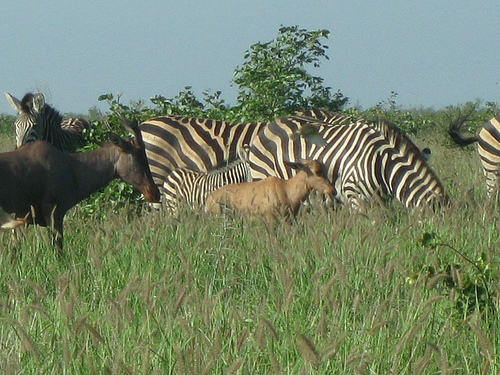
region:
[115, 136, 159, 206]
the head of an animal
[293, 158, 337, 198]
the head of an animal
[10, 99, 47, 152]
the head of an animal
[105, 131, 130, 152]
the ear of an animal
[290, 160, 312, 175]
the ear of an animal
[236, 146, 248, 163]
the ear of an animal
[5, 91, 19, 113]
the ear of an animal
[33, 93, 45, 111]
the ear of an animal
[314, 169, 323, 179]
the eye of an animal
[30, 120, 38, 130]
the eye of an animal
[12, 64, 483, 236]
the animals in the grass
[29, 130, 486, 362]
the grass the animals are standing in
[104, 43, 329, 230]
the tall bushes behind the animals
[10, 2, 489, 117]
the blue sky in the background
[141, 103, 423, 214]
the three zebras in the middle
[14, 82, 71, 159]
the zebra whose head is seen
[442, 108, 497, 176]
the only zebras tail that is seen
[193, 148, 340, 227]
the little brown animal beside the zebras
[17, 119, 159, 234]
the bigger brown animal beside the zebras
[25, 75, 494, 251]
the animals grazing in the field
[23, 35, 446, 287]
animals out in field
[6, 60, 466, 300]
different animals out in field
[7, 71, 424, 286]
variety of animals out in field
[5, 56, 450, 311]
many animals out in field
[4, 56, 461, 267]
several animals out in field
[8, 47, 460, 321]
mix of animals out in field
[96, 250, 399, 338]
patch of green grass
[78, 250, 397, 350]
patch of grass in field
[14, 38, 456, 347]
animals out in tall grass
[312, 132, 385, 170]
stripes of a zebra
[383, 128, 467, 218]
neck of a zebra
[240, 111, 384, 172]
body of a zebra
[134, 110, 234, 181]
body of a zebra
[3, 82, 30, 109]
ear of a zebra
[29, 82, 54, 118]
ear of a zebra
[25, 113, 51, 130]
eye of a zebra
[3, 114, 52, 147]
head of a zebra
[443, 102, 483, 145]
tail of a zebra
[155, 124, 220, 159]
skin of a zebra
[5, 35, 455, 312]
Animals standing in tall grass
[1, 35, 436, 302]
Zebras and ram standing in grass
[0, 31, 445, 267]
Rams standing in front of zebra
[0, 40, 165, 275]
Ram stares in front of zebra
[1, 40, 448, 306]
Zebras eating grass in background of ram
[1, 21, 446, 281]
Zebras eating grass next to bushes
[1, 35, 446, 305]
Zebras walking with young rams.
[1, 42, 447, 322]
Young brown ram walks next to young zebra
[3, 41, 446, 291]
Baby zebra and baby ram walk with older zebra and ram.